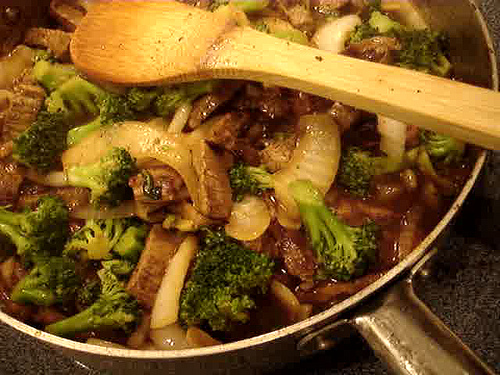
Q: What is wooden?
A: A spoon.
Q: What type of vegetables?
A: Broccoli and onions.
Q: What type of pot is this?
A: A silver pot.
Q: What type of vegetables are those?
A: Onions and broccoli.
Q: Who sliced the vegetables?
A: The chef.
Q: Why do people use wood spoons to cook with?
A: Metal gets to hot.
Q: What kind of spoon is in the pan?
A: A wooden spoon.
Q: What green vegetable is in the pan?
A: Broccoli.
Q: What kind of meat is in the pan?
A: Beef.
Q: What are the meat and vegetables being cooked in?
A: A pan.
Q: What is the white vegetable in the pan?
A: Onions.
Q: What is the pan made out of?
A: Metal.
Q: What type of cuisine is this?
A: Asian.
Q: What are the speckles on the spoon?
A: Bits of food.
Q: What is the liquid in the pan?
A: Sauce.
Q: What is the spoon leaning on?
A: The pan.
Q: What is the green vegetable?
A: Broccoli.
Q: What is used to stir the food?
A: A wooden spoon.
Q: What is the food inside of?
A: A silver skillet.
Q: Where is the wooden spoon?
A: In the pot.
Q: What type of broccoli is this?
A: Florets.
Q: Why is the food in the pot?
A: It is cooking.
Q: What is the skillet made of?
A: Metal.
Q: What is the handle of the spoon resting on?
A: The skillet.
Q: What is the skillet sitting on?
A: A gray countertop.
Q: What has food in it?
A: Metal pot.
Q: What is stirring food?
A: Light wooden spoon.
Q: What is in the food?
A: Green broccoli.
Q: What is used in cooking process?
A: Wooden spoon.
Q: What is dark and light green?
A: Broccoli.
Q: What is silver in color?
A: Handle of pot.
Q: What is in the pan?
A: Stir-fry.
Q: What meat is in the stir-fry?
A: Beef.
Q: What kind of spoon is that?
A: Wooden.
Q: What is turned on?
A: Lights.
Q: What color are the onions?
A: Clear.